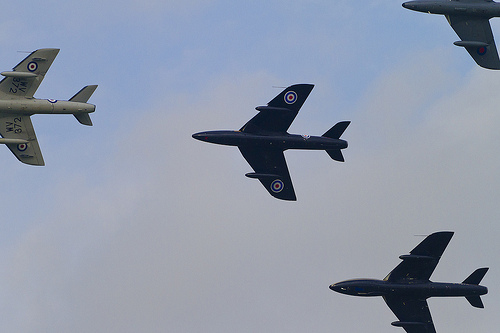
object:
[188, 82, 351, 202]
jet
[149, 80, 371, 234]
middle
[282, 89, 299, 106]
bullseye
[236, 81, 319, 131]
wing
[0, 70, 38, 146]
jet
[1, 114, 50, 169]
wings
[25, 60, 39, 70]
red dot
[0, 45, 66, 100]
wing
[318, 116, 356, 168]
tail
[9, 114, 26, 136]
372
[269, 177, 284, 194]
bullseyes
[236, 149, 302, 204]
wings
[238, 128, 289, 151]
fuel tanks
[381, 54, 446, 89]
clouds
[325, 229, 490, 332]
jet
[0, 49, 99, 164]
jet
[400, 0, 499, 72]
jet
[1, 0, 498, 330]
skies